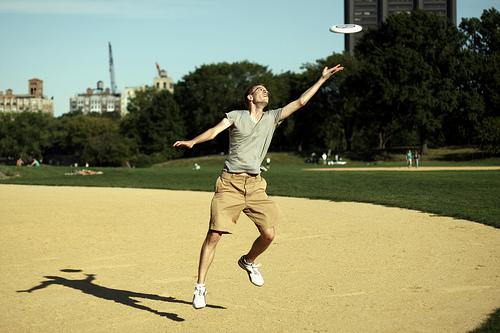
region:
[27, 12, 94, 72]
this is the sky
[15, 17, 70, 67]
the sky is blue in color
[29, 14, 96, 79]
the sky has clouds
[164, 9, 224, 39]
the clouds are white in color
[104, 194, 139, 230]
this is the ground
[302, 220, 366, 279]
the sand is brown in color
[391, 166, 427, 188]
this is the grass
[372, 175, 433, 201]
the grass is green in color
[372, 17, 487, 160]
these are some trees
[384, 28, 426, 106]
the leaves are green in color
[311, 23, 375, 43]
disc in the air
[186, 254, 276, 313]
feet off the ground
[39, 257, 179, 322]
shadow on the ground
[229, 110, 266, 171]
green shirt on the person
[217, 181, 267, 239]
tan shorts worn by the man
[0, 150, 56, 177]
people sitting on the grass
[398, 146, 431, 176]
two people walking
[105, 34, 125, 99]
construction equipment in the distance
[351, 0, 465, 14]
tall building behind the trees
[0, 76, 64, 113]
brown building on the right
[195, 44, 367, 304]
man throwing a frisbeel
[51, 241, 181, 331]
shadow of the man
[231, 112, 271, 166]
blouse is dull green in color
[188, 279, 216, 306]
shoes are white in color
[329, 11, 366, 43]
frisbeel is white in color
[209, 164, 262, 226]
short is brown in color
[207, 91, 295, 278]
man is dressed in a short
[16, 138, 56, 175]
two people seated at the end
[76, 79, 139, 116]
buildings apper far from the view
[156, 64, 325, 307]
this is a man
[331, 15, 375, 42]
this is a frisbee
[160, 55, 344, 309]
the man is on air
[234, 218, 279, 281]
this is the leg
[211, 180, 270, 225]
this is the short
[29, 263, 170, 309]
this is a shadow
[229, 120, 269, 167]
this is a t shirt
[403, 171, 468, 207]
this is the grass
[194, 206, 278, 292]
the legs are apart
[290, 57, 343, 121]
the hand is raised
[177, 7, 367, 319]
Guy trying to catch frisbee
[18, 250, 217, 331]
Guys shadow on ground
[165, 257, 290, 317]
White shoes on mans feet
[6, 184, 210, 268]
Sand on ground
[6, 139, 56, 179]
People sitting in grass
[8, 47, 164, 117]
Buildings in the distance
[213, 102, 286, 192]
Man has on gray shirt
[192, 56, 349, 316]
Man reaching in the air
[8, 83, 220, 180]
Trees in the distance